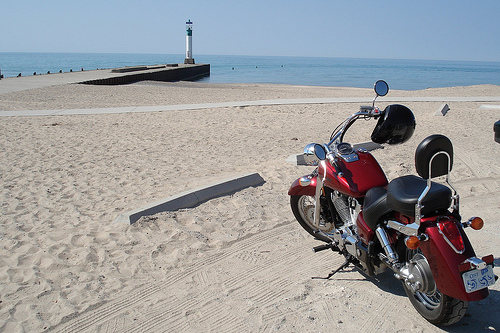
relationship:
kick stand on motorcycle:
[308, 257, 350, 279] [280, 79, 494, 324]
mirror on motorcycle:
[374, 80, 390, 97] [280, 79, 494, 324]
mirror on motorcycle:
[307, 142, 324, 159] [280, 79, 494, 324]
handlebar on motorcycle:
[321, 95, 378, 169] [280, 79, 494, 324]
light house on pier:
[184, 18, 195, 64] [2, 58, 209, 85]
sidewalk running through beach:
[21, 76, 359, 130] [0, 81, 500, 333]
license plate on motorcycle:
[462, 265, 498, 293] [280, 79, 494, 324]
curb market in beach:
[123, 170, 268, 225] [0, 81, 500, 333]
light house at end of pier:
[184, 18, 195, 64] [1, 52, 213, 106]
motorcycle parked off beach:
[287, 80, 499, 327] [7, 55, 399, 235]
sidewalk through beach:
[0, 95, 500, 117] [187, 227, 291, 263]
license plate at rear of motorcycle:
[462, 265, 498, 293] [280, 79, 494, 324]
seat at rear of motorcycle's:
[347, 131, 465, 227] [283, 75, 498, 331]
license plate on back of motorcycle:
[462, 265, 498, 293] [280, 79, 494, 324]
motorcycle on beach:
[280, 79, 494, 324] [1, 64, 499, 329]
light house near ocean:
[184, 18, 195, 64] [0, 0, 499, 85]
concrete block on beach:
[437, 103, 448, 114] [1, 64, 499, 329]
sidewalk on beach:
[0, 95, 500, 117] [7, 87, 498, 331]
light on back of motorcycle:
[467, 215, 485, 228] [280, 79, 494, 324]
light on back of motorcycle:
[400, 233, 417, 248] [280, 79, 494, 324]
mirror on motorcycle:
[369, 78, 391, 102] [280, 79, 494, 324]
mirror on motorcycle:
[314, 144, 327, 160] [280, 79, 494, 324]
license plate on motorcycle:
[458, 264, 498, 292] [280, 79, 494, 324]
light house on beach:
[180, 13, 196, 64] [65, 64, 497, 101]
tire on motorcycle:
[285, 175, 342, 244] [280, 79, 494, 324]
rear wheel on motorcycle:
[402, 254, 467, 326] [280, 79, 494, 324]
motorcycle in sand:
[287, 80, 499, 327] [28, 214, 163, 314]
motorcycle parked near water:
[280, 79, 494, 324] [257, 59, 334, 85]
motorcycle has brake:
[280, 79, 494, 324] [312, 223, 362, 263]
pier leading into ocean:
[2, 58, 209, 85] [4, 50, 499, 87]